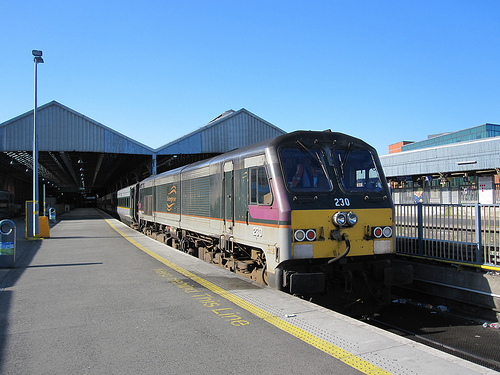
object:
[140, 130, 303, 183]
roof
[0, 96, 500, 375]
train station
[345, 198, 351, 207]
number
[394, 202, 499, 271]
fence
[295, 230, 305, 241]
headlights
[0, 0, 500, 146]
sky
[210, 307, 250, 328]
words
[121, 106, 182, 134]
cloud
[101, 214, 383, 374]
line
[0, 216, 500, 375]
platform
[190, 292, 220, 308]
writing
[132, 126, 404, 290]
train engine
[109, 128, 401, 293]
train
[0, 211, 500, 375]
ground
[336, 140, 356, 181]
wipers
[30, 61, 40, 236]
light post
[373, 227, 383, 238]
lights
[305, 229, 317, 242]
lights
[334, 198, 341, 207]
number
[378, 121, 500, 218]
structure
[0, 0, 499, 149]
clouds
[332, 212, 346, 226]
lights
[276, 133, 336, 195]
windows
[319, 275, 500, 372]
railroad